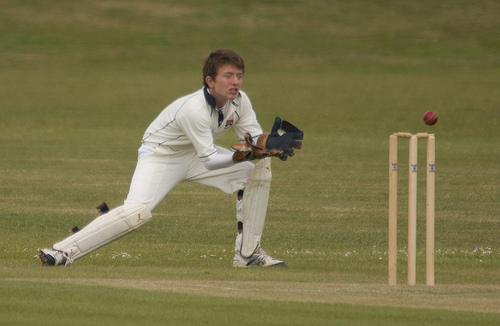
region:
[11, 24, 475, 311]
a young athletic man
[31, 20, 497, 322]
a man playing cricket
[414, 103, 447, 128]
a small red ball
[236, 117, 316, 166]
blue and brown gloves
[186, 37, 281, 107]
a man with short dark hair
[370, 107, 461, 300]
a few wood poles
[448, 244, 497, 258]
clusters of small white flowers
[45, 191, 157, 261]
long white shin guards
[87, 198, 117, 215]
dark blue velcro straps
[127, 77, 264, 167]
a white and blue polo shirt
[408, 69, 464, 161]
Red ball flying threw the air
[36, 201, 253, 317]
Shine guards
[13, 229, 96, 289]
Cleats on the player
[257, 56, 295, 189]
Catching gloves on the player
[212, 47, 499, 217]
Player catching the ball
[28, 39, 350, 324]
Player on the field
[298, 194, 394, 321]
Green grass on the playing feild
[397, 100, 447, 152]
Red ball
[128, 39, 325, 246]
Player in the white uniform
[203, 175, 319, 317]
Sneakers on the field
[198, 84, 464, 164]
Catching the ball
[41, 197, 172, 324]
Shin guards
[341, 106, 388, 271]
Grass playing field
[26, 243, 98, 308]
Cleats on the player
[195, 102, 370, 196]
Catching gloves on the player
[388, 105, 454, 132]
A red ball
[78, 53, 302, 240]
The player is catching the ball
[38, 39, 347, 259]
The player had brown hair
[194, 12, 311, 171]
Player to catch the ball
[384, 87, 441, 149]
Red ball in the air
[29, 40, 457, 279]
man playing cricket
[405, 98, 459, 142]
red cricket ball with white stripes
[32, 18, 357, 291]
cricket player wearing uniform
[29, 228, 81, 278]
white sneaker cleats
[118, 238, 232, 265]
little white flowers in green grassy field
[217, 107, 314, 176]
black and brown cricket mitts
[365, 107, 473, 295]
set of three cricket poles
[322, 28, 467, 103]
large green grassy field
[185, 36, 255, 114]
man with brown hair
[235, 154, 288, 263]
white shin protectors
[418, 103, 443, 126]
ball is small and red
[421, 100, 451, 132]
ball is small and red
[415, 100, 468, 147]
ball is small and red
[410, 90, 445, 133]
ball is small and red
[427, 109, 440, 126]
ball is small and red